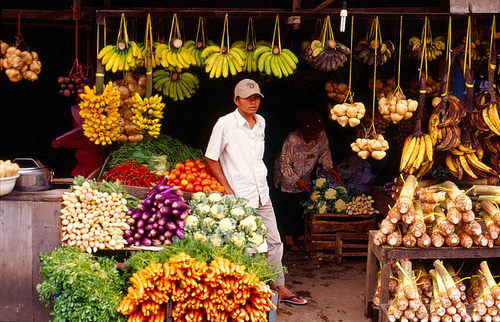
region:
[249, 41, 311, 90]
a bunch of bananas.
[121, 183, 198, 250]
a pile of egg plant.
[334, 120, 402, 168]
produce in a market.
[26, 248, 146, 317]
a bunch of green produce.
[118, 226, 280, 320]
a pile of carrots.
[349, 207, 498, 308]
a pile or produce at a market.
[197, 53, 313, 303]
a man standing in a market.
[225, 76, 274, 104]
a brown cap.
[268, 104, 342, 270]
a woman standing in a store.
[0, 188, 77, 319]
a wooden stand.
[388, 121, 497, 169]
The bananas are white.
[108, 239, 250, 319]
The carrots are orange.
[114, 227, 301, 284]
The tops are green.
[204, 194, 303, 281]
The cabbage is white.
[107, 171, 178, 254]
The eggplant is purple.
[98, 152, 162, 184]
The peppers are red.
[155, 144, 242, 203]
The tomatoes are red.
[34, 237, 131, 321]
The lettuce is green.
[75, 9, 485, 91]
The bananas are hanging.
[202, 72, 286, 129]
The man is wearing a hat.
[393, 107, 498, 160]
The bananas are yellow.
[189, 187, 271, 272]
The cabage is white.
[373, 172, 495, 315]
The leeks are white.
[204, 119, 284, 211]
He has a white shirt.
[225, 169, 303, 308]
He is wearing grey pants.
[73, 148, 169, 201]
The peppers are red.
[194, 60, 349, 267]
A young man standing among fruit and veggies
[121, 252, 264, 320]
A pile of carrots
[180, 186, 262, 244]
A pile of cauliflower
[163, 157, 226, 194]
A pile of tomatoes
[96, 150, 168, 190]
A pile of hot red peppers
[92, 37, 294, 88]
Some bananas hanging overhead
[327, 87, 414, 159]
some garlic hanging down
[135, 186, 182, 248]
A pile of eggplants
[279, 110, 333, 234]
A woman looking at the food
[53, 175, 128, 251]
A pile of turnips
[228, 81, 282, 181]
this is a man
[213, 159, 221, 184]
the man is light skinned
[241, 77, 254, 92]
this is a cap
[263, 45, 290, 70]
this is a bunch of banana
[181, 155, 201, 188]
these are the tomato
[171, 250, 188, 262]
this is a carrot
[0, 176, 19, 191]
this is a trough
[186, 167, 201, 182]
the tomato is red in color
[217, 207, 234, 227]
this is a cabbage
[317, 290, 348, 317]
this is the floor